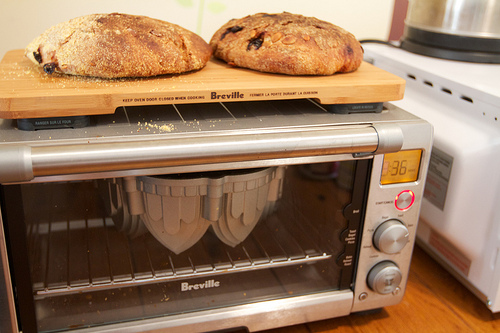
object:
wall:
[0, 0, 396, 54]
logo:
[181, 280, 222, 292]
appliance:
[0, 101, 433, 330]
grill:
[26, 176, 332, 300]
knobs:
[374, 219, 410, 254]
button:
[394, 189, 415, 211]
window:
[379, 148, 423, 185]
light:
[380, 150, 422, 185]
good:
[209, 11, 363, 76]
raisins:
[247, 32, 264, 50]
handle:
[30, 125, 378, 177]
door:
[0, 122, 404, 333]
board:
[0, 49, 405, 119]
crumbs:
[39, 114, 278, 144]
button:
[360, 293, 366, 300]